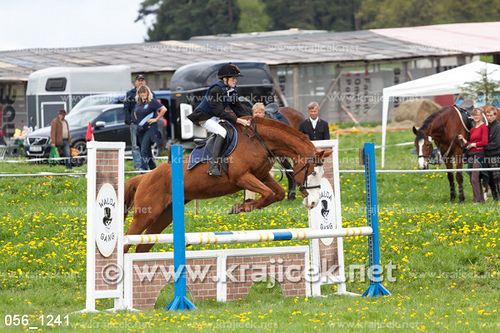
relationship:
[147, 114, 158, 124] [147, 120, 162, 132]
hand on hip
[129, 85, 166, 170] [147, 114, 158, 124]
blonde woman has hand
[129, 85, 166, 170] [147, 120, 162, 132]
blonde woman has hip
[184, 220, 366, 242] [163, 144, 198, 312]
bar between blue pole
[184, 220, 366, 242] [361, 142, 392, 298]
bar between blue pole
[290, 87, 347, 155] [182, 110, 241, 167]
man in jeans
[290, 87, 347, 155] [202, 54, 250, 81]
man in hat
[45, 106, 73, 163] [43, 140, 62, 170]
man holding sack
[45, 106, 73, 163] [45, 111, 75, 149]
man walking in coat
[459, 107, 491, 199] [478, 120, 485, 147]
woman wearing sleeve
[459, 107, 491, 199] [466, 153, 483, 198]
woman wearing pants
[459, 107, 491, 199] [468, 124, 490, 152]
woman wearing shirt